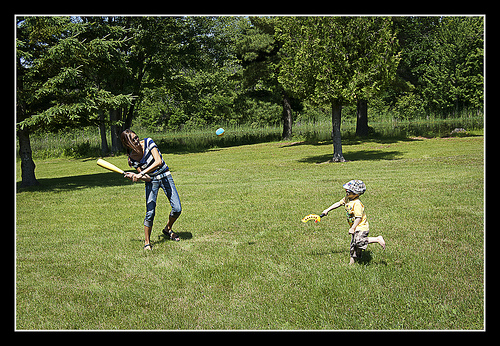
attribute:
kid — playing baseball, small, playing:
[319, 177, 387, 266]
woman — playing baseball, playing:
[118, 127, 183, 252]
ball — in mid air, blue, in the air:
[214, 127, 225, 138]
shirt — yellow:
[340, 197, 369, 232]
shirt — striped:
[128, 139, 170, 181]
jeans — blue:
[141, 175, 182, 227]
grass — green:
[17, 137, 484, 329]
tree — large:
[273, 17, 399, 165]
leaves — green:
[276, 17, 398, 107]